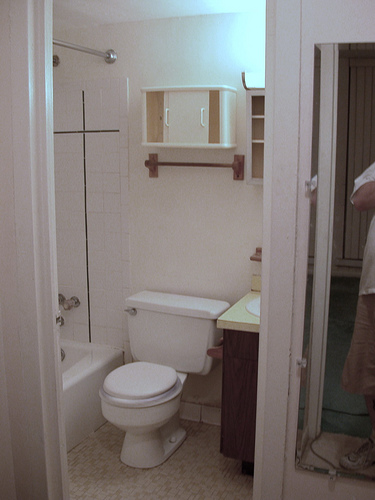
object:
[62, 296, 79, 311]
knob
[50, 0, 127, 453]
shower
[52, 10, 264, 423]
wall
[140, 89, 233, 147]
cabinet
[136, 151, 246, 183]
bar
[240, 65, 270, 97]
portion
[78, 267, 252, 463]
toilet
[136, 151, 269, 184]
handle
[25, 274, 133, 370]
wall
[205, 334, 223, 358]
tissue holder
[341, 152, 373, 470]
adult